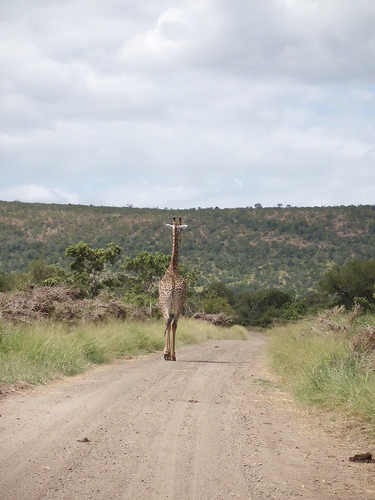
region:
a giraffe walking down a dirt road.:
[148, 210, 193, 363]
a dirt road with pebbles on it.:
[0, 330, 292, 498]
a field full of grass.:
[0, 319, 249, 406]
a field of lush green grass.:
[268, 306, 371, 498]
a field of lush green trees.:
[0, 243, 234, 334]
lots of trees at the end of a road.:
[190, 260, 373, 330]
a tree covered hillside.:
[0, 197, 373, 299]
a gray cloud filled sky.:
[0, 0, 373, 206]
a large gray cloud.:
[0, 112, 372, 172]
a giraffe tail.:
[157, 276, 178, 337]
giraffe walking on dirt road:
[141, 204, 240, 372]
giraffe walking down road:
[155, 206, 210, 366]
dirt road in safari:
[121, 379, 251, 490]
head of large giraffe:
[159, 207, 189, 271]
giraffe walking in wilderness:
[148, 199, 200, 365]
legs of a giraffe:
[157, 314, 184, 358]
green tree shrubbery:
[56, 238, 141, 271]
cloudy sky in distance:
[69, 134, 276, 187]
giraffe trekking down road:
[151, 210, 193, 361]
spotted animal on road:
[159, 200, 190, 371]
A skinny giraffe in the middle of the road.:
[156, 214, 188, 362]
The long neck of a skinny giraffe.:
[169, 231, 180, 269]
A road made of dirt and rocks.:
[0, 326, 372, 496]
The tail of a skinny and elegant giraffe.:
[161, 287, 175, 336]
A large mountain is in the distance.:
[0, 198, 373, 326]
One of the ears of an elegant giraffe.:
[178, 222, 189, 229]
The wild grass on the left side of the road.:
[0, 319, 250, 397]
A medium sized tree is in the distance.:
[63, 238, 123, 272]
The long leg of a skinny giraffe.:
[167, 316, 178, 365]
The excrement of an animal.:
[347, 450, 374, 465]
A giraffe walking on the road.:
[157, 216, 188, 360]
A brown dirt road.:
[0, 327, 369, 498]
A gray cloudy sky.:
[0, 0, 373, 208]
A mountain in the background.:
[0, 198, 374, 304]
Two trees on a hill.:
[63, 238, 201, 286]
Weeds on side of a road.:
[4, 315, 250, 387]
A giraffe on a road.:
[158, 215, 188, 359]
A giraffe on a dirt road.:
[157, 214, 187, 361]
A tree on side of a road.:
[314, 255, 374, 310]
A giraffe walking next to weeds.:
[158, 215, 188, 360]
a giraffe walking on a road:
[147, 207, 203, 368]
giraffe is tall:
[147, 210, 198, 369]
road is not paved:
[35, 332, 287, 499]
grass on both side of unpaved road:
[6, 301, 373, 400]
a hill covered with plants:
[1, 192, 373, 268]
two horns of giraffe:
[160, 211, 188, 237]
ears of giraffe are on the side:
[155, 214, 193, 233]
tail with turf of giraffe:
[159, 275, 182, 344]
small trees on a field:
[54, 232, 152, 285]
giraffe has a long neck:
[159, 213, 187, 274]